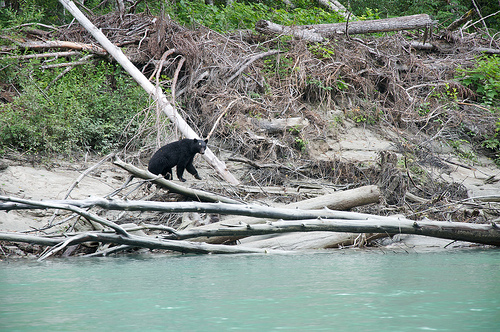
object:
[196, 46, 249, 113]
driftwood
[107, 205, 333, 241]
river bank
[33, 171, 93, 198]
beach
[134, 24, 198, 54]
trees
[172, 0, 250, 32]
bush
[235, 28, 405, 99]
debris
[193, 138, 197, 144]
ear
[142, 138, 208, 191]
bear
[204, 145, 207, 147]
eye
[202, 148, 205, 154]
nose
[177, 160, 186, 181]
front legs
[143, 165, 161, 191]
back legs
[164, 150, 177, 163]
body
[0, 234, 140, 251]
tree logs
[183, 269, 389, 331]
water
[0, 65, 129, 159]
bushes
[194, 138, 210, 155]
head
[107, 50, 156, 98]
tree trunk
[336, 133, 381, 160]
patch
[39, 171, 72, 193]
dirt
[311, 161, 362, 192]
tree limbs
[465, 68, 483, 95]
leaves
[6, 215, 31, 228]
white sand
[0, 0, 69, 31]
tree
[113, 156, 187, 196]
tree trunks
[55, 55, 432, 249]
habitat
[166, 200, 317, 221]
logs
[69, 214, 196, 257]
shoreline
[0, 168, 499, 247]
ground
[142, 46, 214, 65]
tangle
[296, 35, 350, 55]
vines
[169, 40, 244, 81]
branches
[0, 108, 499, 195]
ashore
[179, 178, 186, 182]
feet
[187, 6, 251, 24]
vegetation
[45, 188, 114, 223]
shore